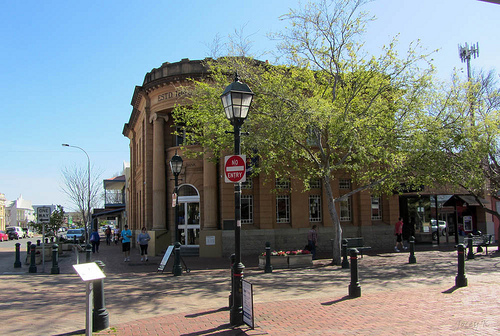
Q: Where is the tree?
A: In front of the building.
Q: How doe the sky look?
A: Clear.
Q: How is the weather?
A: Sunny.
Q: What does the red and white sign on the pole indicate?
A: No entry.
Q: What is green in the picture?
A: Trees.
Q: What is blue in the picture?
A: Sky.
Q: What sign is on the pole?
A: No entry.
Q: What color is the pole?
A: Black.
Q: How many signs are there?
A: One.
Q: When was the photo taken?
A: Day time.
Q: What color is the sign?
A: Red and white.